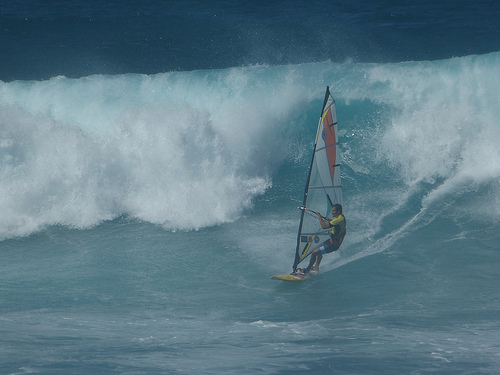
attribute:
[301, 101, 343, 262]
mast — angle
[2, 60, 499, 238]
wave — large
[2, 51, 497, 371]
water — body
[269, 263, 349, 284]
surfboard — wood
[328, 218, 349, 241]
shirt — short sleeve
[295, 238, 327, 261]
knees — bent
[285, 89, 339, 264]
sail — red, white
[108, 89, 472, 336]
wave — large